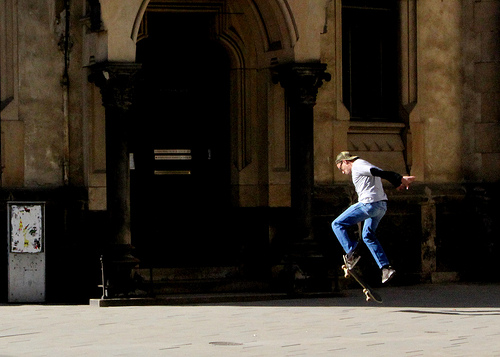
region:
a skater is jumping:
[315, 140, 421, 308]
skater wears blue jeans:
[322, 143, 427, 285]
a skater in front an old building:
[78, 4, 498, 308]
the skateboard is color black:
[335, 258, 384, 306]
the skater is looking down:
[321, 142, 422, 289]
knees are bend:
[323, 213, 385, 244]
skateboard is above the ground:
[333, 258, 393, 320]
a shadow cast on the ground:
[390, 303, 499, 318]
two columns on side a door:
[80, 0, 334, 295]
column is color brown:
[82, 53, 153, 293]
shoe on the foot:
[382, 260, 392, 280]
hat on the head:
[329, 150, 358, 162]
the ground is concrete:
[170, 325, 282, 346]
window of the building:
[317, 4, 405, 129]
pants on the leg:
[362, 222, 384, 257]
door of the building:
[132, 92, 244, 298]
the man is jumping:
[314, 143, 416, 308]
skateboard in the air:
[347, 268, 397, 303]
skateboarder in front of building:
[6, 4, 492, 299]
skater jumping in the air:
[329, 150, 414, 280]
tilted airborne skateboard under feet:
[343, 256, 395, 304]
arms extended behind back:
[361, 160, 416, 190]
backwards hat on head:
[334, 149, 359, 164]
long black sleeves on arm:
[368, 164, 401, 186]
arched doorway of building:
[81, 1, 321, 301]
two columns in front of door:
[97, 59, 329, 296]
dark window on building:
[339, 2, 411, 123]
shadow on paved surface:
[254, 284, 496, 310]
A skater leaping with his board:
[331, 148, 416, 305]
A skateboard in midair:
[341, 253, 388, 305]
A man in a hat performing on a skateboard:
[329, 149, 415, 304]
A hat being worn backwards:
[332, 150, 357, 173]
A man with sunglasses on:
[335, 158, 352, 174]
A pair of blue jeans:
[330, 198, 389, 269]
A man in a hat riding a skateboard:
[329, 148, 415, 303]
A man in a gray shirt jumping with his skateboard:
[329, 148, 415, 302]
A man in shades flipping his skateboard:
[331, 148, 413, 301]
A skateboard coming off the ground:
[340, 251, 386, 306]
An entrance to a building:
[76, 5, 337, 305]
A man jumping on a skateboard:
[315, 128, 440, 323]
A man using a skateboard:
[288, 132, 446, 319]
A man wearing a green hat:
[301, 127, 428, 317]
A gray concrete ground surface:
[163, 310, 355, 352]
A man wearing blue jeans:
[310, 145, 439, 319]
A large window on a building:
[315, 3, 449, 131]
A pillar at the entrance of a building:
[263, 40, 332, 259]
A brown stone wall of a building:
[431, 11, 476, 171]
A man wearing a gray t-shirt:
[317, 136, 422, 306]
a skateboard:
[327, 242, 397, 327]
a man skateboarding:
[322, 134, 419, 326]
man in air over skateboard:
[325, 146, 419, 288]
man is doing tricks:
[325, 142, 420, 289]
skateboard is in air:
[342, 259, 384, 305]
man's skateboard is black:
[343, 259, 385, 308]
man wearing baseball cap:
[332, 145, 357, 166]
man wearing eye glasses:
[335, 155, 342, 170]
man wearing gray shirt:
[343, 150, 389, 205]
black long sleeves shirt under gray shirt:
[367, 166, 404, 187]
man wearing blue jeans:
[327, 194, 394, 269]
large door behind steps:
[116, 2, 240, 267]